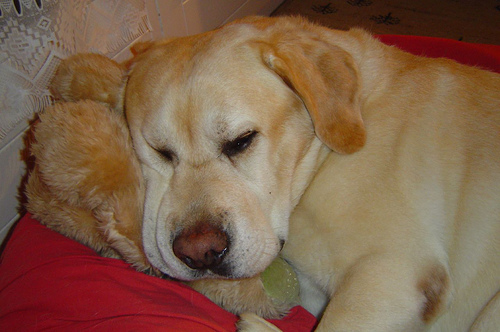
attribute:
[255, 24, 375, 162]
ear — darker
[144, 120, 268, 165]
eyes — closed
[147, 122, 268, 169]
eyes — dark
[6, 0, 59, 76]
design — lace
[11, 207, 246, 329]
bed — red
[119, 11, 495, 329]
dog — yellow, resting, gold, brown, sleeping, laying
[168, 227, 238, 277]
nose — brown, pink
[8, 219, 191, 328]
bed — red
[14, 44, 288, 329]
teddy bear — light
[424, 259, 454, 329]
patch — darker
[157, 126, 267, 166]
eyes — closed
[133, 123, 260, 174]
eyes — half closed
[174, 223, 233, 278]
nose — pink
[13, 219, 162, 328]
cushion — red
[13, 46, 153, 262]
stuffed animal — tan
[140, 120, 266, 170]
eyes — black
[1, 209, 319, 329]
sheets — red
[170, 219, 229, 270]
dog's nose — brown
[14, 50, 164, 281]
stuffed animal — golden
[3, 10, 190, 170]
wall covers — white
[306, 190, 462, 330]
dog's leg — brown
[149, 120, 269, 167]
dog's eyes — closed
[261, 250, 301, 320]
foot — green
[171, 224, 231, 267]
dog's nose — brown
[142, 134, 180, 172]
dog's eye — squished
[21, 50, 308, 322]
stuffed animal — brown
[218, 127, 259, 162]
dog's eye — black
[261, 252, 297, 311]
foot — green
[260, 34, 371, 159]
dog's ear — down